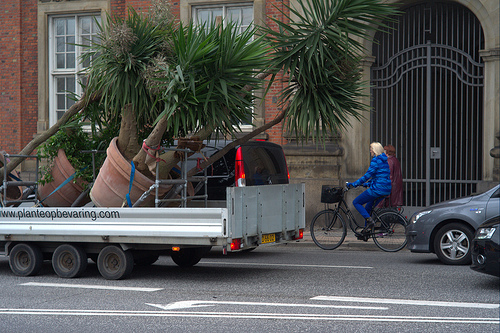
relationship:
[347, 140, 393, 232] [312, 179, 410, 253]
lady on bike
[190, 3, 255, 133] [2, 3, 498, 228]
window on building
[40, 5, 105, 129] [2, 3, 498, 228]
window on building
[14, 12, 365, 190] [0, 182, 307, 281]
potted trees are on a truck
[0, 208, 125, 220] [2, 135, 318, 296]
name on truck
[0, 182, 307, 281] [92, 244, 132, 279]
truck has wheel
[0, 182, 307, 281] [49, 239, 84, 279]
truck has wheel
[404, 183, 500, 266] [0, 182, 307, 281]
car following truck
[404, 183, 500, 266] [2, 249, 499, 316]
car in lane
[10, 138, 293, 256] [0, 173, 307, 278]
black car directly behind truck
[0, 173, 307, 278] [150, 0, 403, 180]
truck with plant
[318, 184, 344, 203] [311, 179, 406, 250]
basket on front of a bicycle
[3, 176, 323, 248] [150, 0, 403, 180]
flatbed with plant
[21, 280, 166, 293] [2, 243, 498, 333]
line on lane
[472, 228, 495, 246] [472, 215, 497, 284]
headlight on a car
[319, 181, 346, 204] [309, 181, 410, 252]
bag on a bicycle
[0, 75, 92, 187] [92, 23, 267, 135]
stem on plant